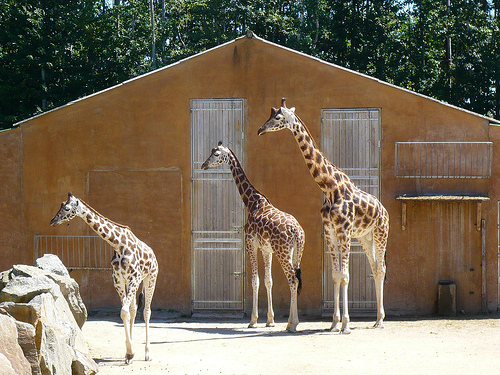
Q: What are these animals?
A: Giraffes.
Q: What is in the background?
A: Building.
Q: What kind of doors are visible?
A: Metal.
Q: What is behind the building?
A: Trees.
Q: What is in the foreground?
A: Rocks.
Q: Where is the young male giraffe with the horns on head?
A: To the left.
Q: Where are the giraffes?
A: By the building.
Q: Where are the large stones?
A: By the small giraffe.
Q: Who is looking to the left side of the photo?
A: The small giraffe.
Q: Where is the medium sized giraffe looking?
A: To the left side of the photo.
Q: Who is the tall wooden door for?
A: Giraffes.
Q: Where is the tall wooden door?
A: Behind the giraffe.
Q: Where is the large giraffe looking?
A: To the left of the photo.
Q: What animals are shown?
A: Giraffes.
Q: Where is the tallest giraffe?
A: On the right.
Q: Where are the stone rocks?
A: To the left of giraffe.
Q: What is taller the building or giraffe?
A: Building.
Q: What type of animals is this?
A: Giraffe.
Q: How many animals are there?
A: Three.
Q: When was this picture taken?
A: Daytime.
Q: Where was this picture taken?
A: Zoo.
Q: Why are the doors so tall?
A: Giraffes can fit.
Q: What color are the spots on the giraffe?
A: Brown.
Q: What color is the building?
A: Brown.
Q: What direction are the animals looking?
A: Left.